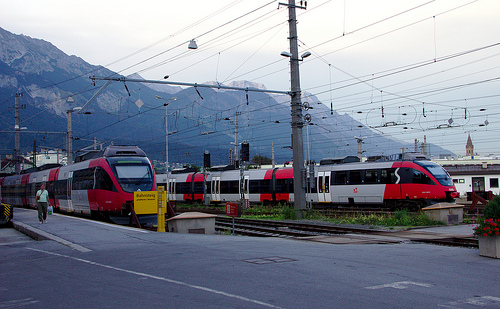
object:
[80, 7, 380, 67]
clouds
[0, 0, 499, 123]
wires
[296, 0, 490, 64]
wires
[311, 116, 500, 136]
wires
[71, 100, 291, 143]
wires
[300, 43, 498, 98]
wires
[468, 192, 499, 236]
bush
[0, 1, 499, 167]
wires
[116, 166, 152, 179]
window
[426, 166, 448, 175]
window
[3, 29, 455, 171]
mountains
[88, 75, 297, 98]
rod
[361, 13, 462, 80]
clouds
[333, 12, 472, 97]
sky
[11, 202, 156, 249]
platform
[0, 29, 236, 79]
banana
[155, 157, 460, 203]
train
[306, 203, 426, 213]
track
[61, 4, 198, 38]
clouds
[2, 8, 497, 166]
sky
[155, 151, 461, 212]
red train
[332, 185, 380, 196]
gray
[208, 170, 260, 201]
gray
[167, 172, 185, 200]
gray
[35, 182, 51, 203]
shirt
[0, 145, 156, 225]
train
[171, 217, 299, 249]
track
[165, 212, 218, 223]
brown roof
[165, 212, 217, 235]
sunken structure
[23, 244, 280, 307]
white line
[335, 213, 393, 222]
grass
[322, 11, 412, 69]
sky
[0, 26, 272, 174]
wall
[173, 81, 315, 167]
wall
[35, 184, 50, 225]
person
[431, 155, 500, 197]
building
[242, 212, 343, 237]
tracks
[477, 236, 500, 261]
planter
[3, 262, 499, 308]
ground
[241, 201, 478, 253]
tracks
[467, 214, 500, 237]
flowers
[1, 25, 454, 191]
mountains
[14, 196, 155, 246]
sidewalk